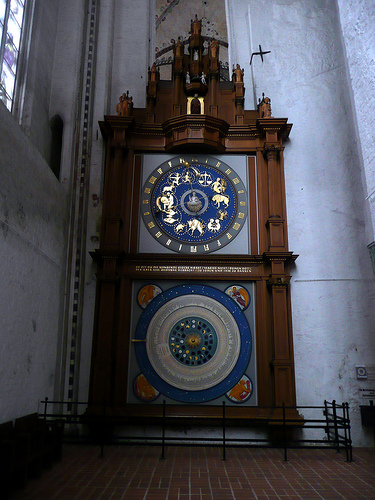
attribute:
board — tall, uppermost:
[70, 65, 329, 427]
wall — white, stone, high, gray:
[305, 32, 341, 130]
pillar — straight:
[28, 1, 139, 416]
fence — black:
[3, 359, 369, 470]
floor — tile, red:
[137, 466, 290, 499]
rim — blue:
[235, 302, 254, 331]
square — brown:
[94, 459, 137, 483]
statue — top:
[122, 23, 308, 176]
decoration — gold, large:
[165, 151, 244, 209]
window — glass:
[7, 5, 19, 41]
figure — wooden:
[181, 34, 240, 95]